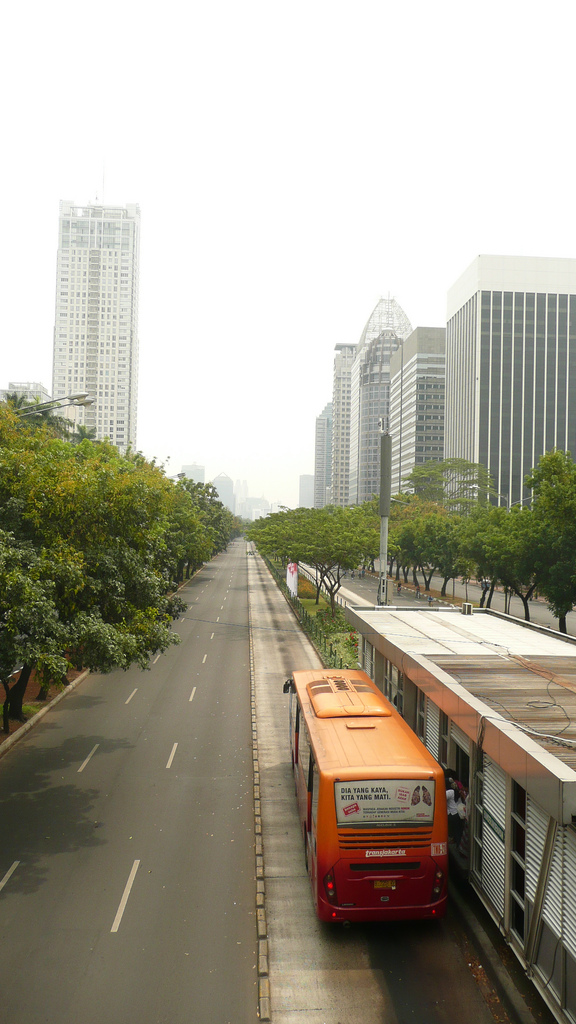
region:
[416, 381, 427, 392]
window overlooking green trees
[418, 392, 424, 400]
window overlooking green trees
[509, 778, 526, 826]
window overlooking green trees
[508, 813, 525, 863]
window overlooking green trees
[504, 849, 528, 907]
window overlooking green trees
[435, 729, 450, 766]
window overlooking green trees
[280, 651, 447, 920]
Orange and red bus at the bus stop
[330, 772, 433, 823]
advertisement on back of bus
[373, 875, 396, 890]
license plate on the bus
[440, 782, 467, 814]
woman wearing a white shirt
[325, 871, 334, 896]
red light on the bus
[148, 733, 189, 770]
white line painted on the street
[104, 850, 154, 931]
white line painted on the street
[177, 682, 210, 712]
white line painted on the street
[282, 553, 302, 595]
White banner hanging from the tree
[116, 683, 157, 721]
white line painted on the street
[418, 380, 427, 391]
A window on a building.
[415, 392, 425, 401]
A window on a building.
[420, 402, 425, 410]
A window on a building.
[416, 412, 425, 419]
A window on a building.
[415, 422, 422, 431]
A window on a building.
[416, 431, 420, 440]
A window on a building.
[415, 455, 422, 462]
A window on a building.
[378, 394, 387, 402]
A window on a building.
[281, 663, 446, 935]
orange and red city bus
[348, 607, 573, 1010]
covered bus station for passengers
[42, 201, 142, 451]
very tall white apartment building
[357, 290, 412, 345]
pyramid shaped top of building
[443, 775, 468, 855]
woman in white shirt getting on bus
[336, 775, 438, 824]
ad on back window of city bus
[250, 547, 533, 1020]
parking lane for buses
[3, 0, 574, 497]
heavily overcast sky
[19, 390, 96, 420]
street lamps sticking out from top of trees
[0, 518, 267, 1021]
long straight three lane road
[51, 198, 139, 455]
Ultra-modern white multi-level building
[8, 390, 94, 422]
A pair of modern street lights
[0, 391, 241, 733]
Long row of trees along a boulevard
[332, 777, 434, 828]
Advertisement on the back of a bus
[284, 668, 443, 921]
Red and orange city bus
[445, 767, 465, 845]
People preparing to board a bus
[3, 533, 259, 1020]
Broad street in a modern city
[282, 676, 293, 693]
Driver's side mirror of a city bus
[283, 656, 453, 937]
orange double decker bus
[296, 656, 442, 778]
orange roof of bus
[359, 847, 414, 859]
white writing on bus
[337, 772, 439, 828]
white ad on bus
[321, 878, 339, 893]
red tail light on bus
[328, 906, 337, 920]
red tail light on bus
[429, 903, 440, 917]
red tail light on bus